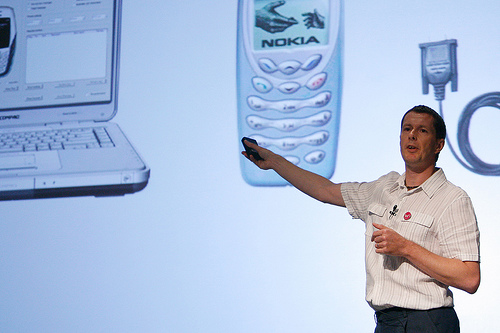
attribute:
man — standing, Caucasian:
[244, 99, 487, 330]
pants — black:
[370, 302, 468, 330]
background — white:
[1, 1, 483, 329]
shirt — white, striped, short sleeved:
[338, 164, 481, 310]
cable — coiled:
[435, 89, 484, 179]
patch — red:
[400, 209, 413, 221]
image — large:
[2, 1, 483, 330]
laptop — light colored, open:
[2, 1, 152, 203]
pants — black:
[371, 304, 462, 331]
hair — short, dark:
[398, 103, 448, 165]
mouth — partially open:
[403, 142, 418, 152]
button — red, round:
[402, 210, 411, 218]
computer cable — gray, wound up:
[416, 38, 483, 178]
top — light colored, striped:
[338, 165, 480, 313]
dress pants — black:
[372, 301, 462, 331]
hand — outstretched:
[240, 137, 273, 172]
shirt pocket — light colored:
[364, 200, 391, 240]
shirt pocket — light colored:
[395, 208, 434, 249]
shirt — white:
[342, 169, 475, 313]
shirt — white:
[332, 160, 479, 303]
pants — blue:
[370, 299, 461, 331]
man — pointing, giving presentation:
[229, 95, 478, 322]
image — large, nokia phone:
[239, 1, 348, 191]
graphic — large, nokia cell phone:
[223, 0, 349, 190]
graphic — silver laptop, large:
[1, 3, 158, 209]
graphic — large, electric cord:
[404, 30, 484, 193]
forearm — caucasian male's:
[355, 179, 481, 296]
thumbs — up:
[366, 217, 390, 227]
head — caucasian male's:
[387, 96, 453, 180]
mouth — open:
[397, 139, 421, 160]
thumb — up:
[362, 213, 392, 231]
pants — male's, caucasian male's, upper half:
[371, 280, 484, 331]